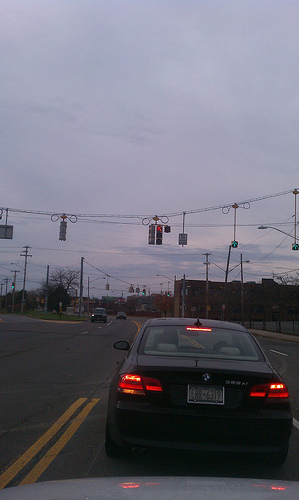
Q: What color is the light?
A: Red.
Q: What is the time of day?
A: Dusk.